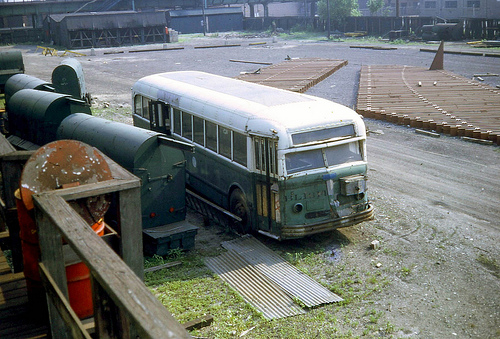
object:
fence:
[196, 246, 306, 322]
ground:
[0, 31, 499, 339]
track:
[355, 62, 499, 142]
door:
[248, 133, 280, 240]